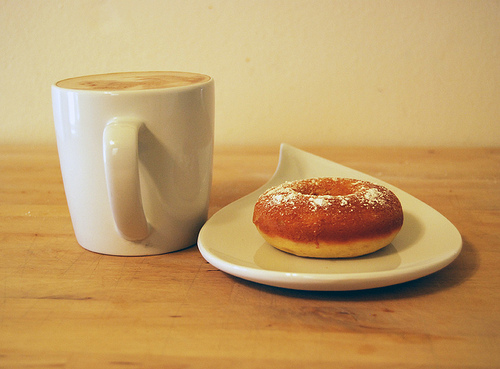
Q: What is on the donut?
A: Sugar.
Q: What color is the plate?
A: White.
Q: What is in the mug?
A: Coffee.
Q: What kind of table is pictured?
A: Wood.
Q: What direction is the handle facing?
A: Forward.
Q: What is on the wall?
A: Paint.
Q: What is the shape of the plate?
A: Teardrop.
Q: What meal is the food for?
A: Breakfast.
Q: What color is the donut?
A: Brown.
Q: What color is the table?
A: Brown.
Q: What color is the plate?
A: White.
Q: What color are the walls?
A: White.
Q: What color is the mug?
A: White.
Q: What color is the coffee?
A: Brown.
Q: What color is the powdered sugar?
A: White.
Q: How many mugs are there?
A: One.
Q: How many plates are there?
A: One.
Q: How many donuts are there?
A: One.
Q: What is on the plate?
A: A donut.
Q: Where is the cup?
A: To the left of the donut.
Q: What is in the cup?
A: Coffee.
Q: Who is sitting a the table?
A: Nobody.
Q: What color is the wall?
A: White.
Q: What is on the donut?
A: Powdered sugar.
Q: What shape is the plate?
A: Round with pointed end.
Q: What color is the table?
A: Brown.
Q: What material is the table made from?
A: Wood.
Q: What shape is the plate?
A: Round.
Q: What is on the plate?
A: Donut.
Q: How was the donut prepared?
A: With powdered sugar.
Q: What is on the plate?
A: A donut.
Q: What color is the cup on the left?
A: White.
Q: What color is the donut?
A: Brown.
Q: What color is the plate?
A: White.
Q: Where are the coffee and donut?
A: Beside each other.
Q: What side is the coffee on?
A: The left side.